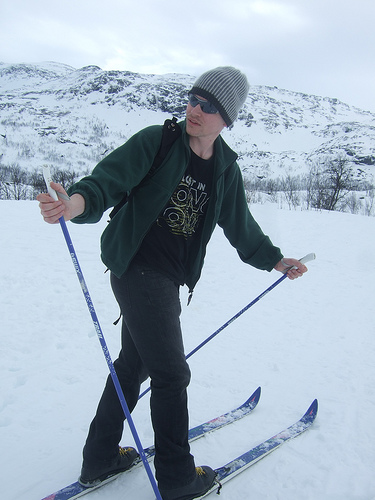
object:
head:
[187, 67, 250, 137]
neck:
[188, 135, 216, 159]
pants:
[82, 259, 196, 487]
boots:
[157, 464, 217, 499]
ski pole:
[138, 252, 315, 400]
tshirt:
[133, 139, 216, 287]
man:
[36, 66, 307, 499]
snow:
[0, 197, 375, 498]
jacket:
[66, 119, 284, 304]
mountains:
[0, 59, 374, 214]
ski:
[194, 397, 317, 499]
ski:
[39, 385, 261, 499]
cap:
[187, 66, 250, 130]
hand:
[277, 256, 306, 280]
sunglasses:
[186, 91, 218, 116]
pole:
[42, 164, 163, 499]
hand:
[37, 182, 70, 225]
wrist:
[71, 193, 83, 221]